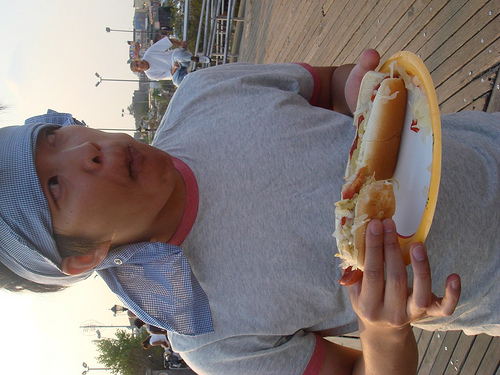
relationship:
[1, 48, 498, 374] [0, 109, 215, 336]
boy has a bandana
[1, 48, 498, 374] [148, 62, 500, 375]
boy has a shirt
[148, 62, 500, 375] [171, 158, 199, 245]
shirt has a pink collar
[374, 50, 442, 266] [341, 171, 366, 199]
plate has hot dog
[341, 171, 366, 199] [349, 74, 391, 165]
hot dog have ketchup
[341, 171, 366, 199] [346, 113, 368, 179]
hot dog have mustard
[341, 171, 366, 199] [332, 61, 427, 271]
hot dog have onion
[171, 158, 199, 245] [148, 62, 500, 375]
pink collar on shirt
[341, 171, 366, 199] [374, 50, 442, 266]
hot dog are on plate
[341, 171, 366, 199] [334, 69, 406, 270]
hot dog have buns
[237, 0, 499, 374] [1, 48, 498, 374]
deck behind boy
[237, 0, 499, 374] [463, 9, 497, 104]
deck has nails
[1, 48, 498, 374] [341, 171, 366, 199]
boy holding hot dog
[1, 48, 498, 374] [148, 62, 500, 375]
boy wearing shirt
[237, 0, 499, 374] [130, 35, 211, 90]
deck below man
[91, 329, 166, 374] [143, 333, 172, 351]
tree behind a woman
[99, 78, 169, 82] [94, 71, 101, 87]
pole has lights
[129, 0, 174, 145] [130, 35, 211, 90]
buildings are behind man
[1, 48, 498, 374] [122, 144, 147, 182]
boy has a mouth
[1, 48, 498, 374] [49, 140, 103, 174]
boy has a nose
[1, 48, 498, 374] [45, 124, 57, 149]
boy has an eye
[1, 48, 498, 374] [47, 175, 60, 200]
boy has an eye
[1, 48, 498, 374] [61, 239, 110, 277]
boy has an ear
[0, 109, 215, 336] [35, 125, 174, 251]
bandana on h head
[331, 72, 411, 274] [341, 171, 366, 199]
buns for hot dog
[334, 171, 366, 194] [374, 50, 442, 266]
hot dog on a plate